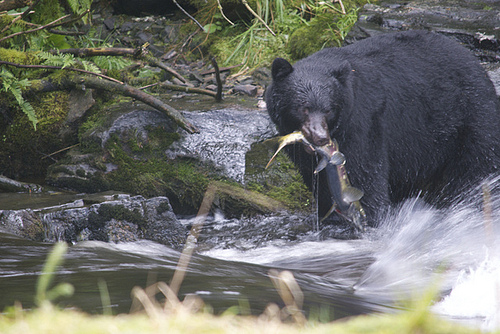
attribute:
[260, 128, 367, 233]
fish — long, thin, dead, black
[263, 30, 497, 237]
bear — black, fishing, wet, looking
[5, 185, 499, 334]
water — splashing, flowing, moving, spraying, fast, dark brown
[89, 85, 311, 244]
rocks — glistening, mossy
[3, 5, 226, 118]
branches — broken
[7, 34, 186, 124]
roots — mossy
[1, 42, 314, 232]
moss — green, dark green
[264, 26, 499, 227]
fur — wet